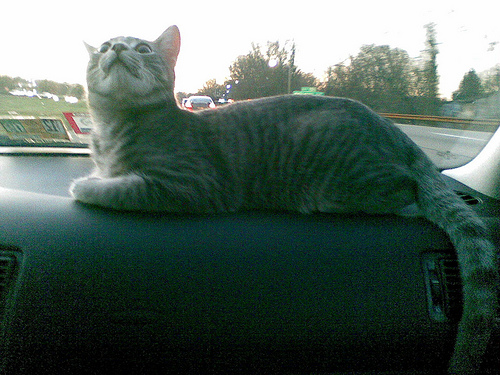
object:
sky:
[193, 0, 420, 35]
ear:
[153, 25, 181, 69]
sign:
[293, 87, 326, 96]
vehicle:
[182, 96, 216, 108]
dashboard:
[79, 208, 392, 372]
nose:
[112, 43, 126, 54]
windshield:
[0, 0, 499, 198]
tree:
[175, 37, 323, 107]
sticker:
[0, 117, 72, 142]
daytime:
[0, 0, 240, 86]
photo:
[0, 0, 500, 375]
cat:
[70, 25, 500, 375]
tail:
[417, 181, 496, 375]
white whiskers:
[68, 52, 111, 97]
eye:
[135, 44, 152, 53]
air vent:
[423, 248, 464, 326]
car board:
[2, 197, 499, 375]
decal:
[58, 104, 92, 137]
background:
[0, 0, 499, 125]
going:
[0, 125, 500, 316]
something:
[105, 57, 140, 80]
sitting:
[154, 208, 482, 221]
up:
[99, 41, 135, 59]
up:
[161, 46, 181, 77]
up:
[68, 54, 171, 99]